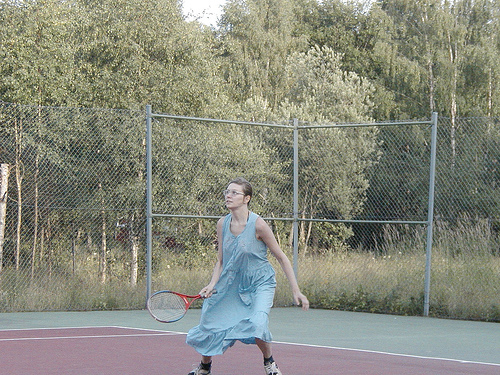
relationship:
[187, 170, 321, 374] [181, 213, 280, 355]
person wears dress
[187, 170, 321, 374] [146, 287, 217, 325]
person holds racket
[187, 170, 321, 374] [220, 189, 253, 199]
person wears glasses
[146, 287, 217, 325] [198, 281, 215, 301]
racket in right hand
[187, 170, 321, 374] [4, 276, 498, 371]
person plays tennis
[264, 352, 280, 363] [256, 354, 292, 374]
sock on left foot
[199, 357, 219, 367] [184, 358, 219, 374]
sock on right foot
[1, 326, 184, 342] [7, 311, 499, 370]
lines are painted on ground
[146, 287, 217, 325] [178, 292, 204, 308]
racket has red handle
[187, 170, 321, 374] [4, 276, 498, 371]
person playing tennis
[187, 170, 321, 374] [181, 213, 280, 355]
person wearing dress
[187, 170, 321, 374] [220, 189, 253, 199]
person wearing glasses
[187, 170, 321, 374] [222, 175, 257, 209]
person has head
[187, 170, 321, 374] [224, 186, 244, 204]
person has face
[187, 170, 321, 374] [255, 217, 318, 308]
person has left arm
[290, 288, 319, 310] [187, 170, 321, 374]
left hand from person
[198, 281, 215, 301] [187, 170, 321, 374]
right hand from person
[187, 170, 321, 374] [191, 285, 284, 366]
person has legs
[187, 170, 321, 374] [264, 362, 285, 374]
person wears shoe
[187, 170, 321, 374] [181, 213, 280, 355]
person in dress